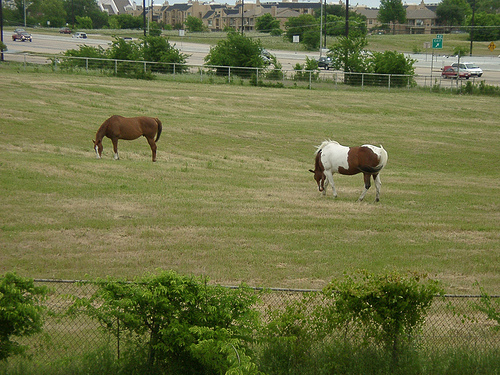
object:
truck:
[12, 29, 32, 43]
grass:
[2, 220, 203, 303]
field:
[2, 0, 500, 375]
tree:
[61, 44, 108, 70]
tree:
[106, 35, 146, 79]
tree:
[143, 28, 194, 73]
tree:
[204, 29, 262, 78]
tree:
[326, 22, 368, 82]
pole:
[456, 49, 460, 94]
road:
[267, 47, 287, 64]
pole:
[430, 33, 435, 92]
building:
[401, 3, 438, 35]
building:
[351, 3, 383, 33]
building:
[274, 5, 303, 32]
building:
[164, 3, 193, 30]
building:
[202, 3, 239, 35]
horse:
[92, 112, 162, 163]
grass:
[359, 101, 492, 196]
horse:
[307, 126, 404, 204]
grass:
[0, 59, 117, 165]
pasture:
[3, 60, 499, 287]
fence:
[4, 278, 500, 372]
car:
[450, 61, 483, 77]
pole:
[174, 64, 176, 76]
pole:
[257, 69, 258, 85]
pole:
[86, 57, 89, 72]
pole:
[256, 69, 258, 86]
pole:
[388, 75, 390, 88]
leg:
[145, 134, 157, 162]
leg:
[111, 140, 117, 160]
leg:
[358, 169, 371, 202]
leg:
[373, 172, 381, 202]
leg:
[323, 169, 339, 199]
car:
[256, 50, 271, 65]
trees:
[378, 0, 404, 35]